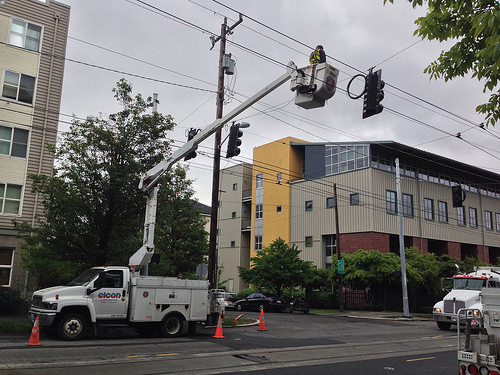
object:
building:
[287, 141, 499, 311]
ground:
[0, 310, 474, 374]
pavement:
[0, 311, 465, 374]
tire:
[58, 315, 90, 342]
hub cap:
[66, 317, 80, 335]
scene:
[0, 0, 499, 374]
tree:
[11, 79, 210, 287]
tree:
[239, 236, 319, 300]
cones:
[211, 313, 227, 338]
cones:
[24, 315, 45, 344]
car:
[235, 291, 288, 311]